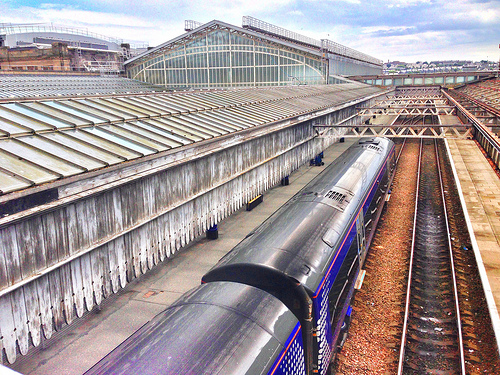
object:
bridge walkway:
[338, 71, 500, 86]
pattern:
[317, 280, 332, 373]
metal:
[82, 279, 304, 374]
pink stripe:
[270, 324, 302, 374]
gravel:
[364, 320, 369, 325]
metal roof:
[0, 83, 383, 194]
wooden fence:
[0, 90, 397, 361]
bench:
[245, 194, 264, 211]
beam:
[313, 124, 472, 127]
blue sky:
[0, 0, 499, 64]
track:
[397, 139, 425, 374]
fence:
[320, 38, 382, 66]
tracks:
[432, 139, 466, 374]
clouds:
[0, 0, 499, 64]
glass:
[291, 65, 294, 77]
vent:
[323, 189, 346, 202]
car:
[77, 279, 305, 374]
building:
[1, 84, 397, 361]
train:
[79, 136, 397, 374]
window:
[253, 53, 279, 67]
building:
[121, 19, 383, 91]